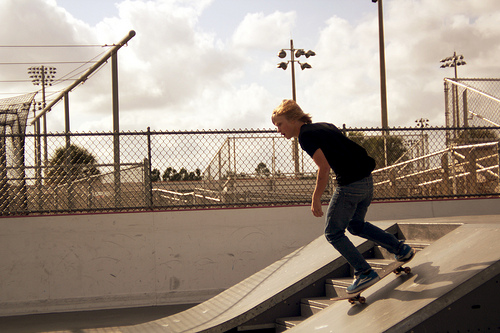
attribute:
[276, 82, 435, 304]
kid — young 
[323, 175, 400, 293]
jeans — blue 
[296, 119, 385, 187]
shirt — black 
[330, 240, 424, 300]
skateboard — dark , gray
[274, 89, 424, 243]
boy — young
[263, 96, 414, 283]
boy — young, blond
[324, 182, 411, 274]
jeans — blue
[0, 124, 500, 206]
railings — steel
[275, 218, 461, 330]
stairs — cement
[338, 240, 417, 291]
shoes — blue 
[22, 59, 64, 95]
lighting — bright, overhead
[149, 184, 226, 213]
metal handrail — metallic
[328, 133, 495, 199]
metal handrail — metallic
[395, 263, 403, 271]
wheel — back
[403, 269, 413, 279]
wheel — back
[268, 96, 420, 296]
boy — young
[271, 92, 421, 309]
boy — Young 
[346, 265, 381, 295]
sneaker — blue, white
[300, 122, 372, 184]
t-shirt — black, short sleeved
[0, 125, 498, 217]
fence — silver, chainlink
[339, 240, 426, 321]
shoes — blue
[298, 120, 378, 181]
tshirt — black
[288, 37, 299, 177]
pole — metallic, grey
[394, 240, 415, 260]
sneaker — blue, white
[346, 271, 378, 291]
sneaker — blue, white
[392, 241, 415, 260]
shoe — blue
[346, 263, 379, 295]
shoe — blue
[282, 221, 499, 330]
ramp — cement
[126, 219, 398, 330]
ramp — cement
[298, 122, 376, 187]
shirt — black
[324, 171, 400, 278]
jeans — blue